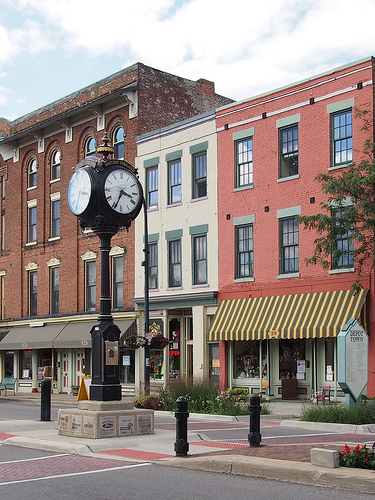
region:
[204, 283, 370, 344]
the awning is green and yellow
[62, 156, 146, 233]
the clock is big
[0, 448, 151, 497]
white lines on the crosswalk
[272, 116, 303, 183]
the window is open on the red building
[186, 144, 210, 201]
the window is open on the white building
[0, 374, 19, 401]
a bench in front of the window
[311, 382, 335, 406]
the chair is blue and red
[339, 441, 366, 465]
the flowers are red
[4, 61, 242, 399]
the taller part of the building is brown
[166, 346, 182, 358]
the open sign is glowing red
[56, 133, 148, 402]
A clock pole next to the street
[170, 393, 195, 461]
A short black pole on the median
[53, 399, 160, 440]
The grey stone base of the clock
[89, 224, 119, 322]
The slender black middle section of the clock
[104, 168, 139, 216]
A white clock face on the pole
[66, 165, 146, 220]
Two circular clocks are visible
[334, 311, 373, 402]
A large blue and white sign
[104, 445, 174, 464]
A small red section of pavement near the clock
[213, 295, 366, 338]
A striped awning on the red building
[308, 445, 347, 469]
A small grey block on the median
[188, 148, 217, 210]
window on the building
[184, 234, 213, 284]
window on the building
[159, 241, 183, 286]
window on the building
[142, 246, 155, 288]
window on the building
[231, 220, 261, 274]
window on the building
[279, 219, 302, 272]
window on the building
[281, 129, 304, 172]
window on the building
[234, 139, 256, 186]
window on the building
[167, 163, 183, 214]
window on the building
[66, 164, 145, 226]
two white and black clocks on metal pole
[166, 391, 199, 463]
black pole in sidewalk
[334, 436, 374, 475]
small bed of red flowers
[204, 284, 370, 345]
green and yellow awning on front of building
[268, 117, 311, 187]
open window on front of brick building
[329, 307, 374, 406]
grey and green metal sign on sidewalk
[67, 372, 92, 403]
yellow triangle on sidewalk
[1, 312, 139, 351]
long brown awning on front of brick building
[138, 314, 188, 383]
window on front of building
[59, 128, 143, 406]
two clocks on top of black metal pole